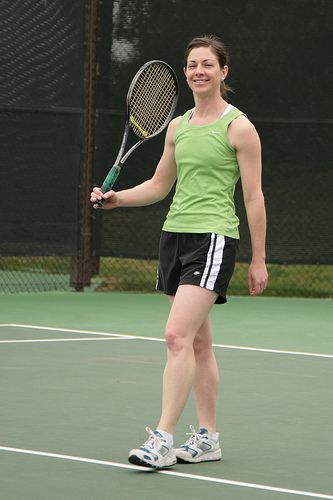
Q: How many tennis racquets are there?
A: One racquet.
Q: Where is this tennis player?
A: On a tennis court.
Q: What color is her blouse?
A: Green.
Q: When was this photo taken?
A: In the daytime.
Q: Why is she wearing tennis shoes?
A: Keep from slipping.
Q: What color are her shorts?
A: Black and white.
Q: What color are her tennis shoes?
A: White and blue.